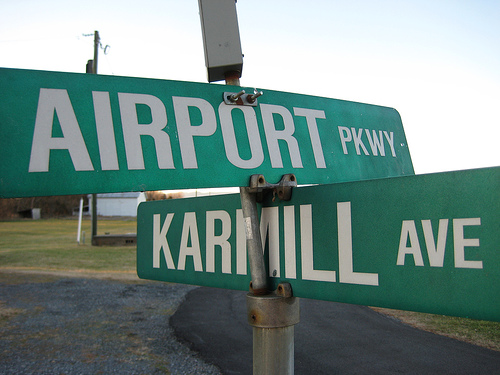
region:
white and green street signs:
[3, 64, 499, 304]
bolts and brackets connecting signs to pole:
[223, 79, 304, 302]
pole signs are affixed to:
[247, 297, 291, 373]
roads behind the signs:
[2, 259, 499, 373]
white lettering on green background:
[25, 77, 482, 293]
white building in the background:
[88, 189, 141, 220]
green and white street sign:
[0, 66, 418, 203]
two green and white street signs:
[1, 65, 498, 321]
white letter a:
[25, 85, 92, 177]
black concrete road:
[165, 282, 499, 374]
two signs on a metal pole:
[0, 65, 498, 371]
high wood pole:
[80, 25, 112, 252]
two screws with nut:
[220, 89, 267, 110]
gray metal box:
[191, 0, 247, 79]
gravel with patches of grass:
[2, 277, 219, 373]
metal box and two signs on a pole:
[0, 2, 498, 372]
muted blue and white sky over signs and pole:
[7, 6, 495, 176]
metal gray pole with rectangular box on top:
[196, 1, 307, 368]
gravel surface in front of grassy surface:
[7, 216, 218, 369]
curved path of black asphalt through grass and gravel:
[173, 286, 494, 368]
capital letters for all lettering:
[23, 83, 484, 308]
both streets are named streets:
[27, 81, 485, 294]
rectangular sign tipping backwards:
[9, 55, 419, 209]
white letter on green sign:
[20, 69, 94, 209]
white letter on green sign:
[80, 78, 141, 188]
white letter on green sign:
[120, 79, 184, 200]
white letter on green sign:
[161, 83, 225, 191]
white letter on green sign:
[227, 86, 274, 178]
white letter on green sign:
[262, 93, 306, 181]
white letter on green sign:
[288, 101, 333, 198]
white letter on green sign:
[141, 209, 179, 299]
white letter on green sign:
[178, 192, 209, 307]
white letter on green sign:
[204, 202, 245, 286]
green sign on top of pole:
[1, 65, 421, 205]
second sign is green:
[132, 158, 499, 331]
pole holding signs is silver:
[234, 187, 306, 374]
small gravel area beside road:
[2, 269, 222, 374]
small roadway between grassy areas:
[171, 279, 499, 374]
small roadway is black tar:
[168, 277, 499, 374]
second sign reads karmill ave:
[126, 163, 498, 329]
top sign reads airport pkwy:
[0, 65, 422, 195]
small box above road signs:
[193, 0, 250, 86]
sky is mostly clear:
[1, 2, 499, 204]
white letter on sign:
[21, 81, 96, 176]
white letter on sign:
[151, 211, 175, 271]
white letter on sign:
[175, 209, 205, 272]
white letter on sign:
[203, 210, 231, 277]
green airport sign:
[8, 65, 424, 185]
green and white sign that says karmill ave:
[128, 159, 493, 324]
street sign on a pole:
[221, 120, 368, 339]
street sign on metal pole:
[234, 172, 361, 369]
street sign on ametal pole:
[193, 141, 360, 368]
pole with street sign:
[205, 184, 343, 368]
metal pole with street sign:
[225, 158, 347, 368]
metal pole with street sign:
[198, 151, 337, 371]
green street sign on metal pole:
[133, 99, 411, 329]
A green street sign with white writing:
[0, 94, 420, 346]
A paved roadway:
[131, 304, 370, 353]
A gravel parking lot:
[85, 283, 164, 330]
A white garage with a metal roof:
[81, 184, 152, 231]